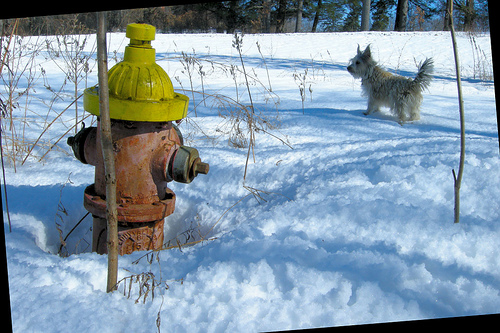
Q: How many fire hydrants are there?
A: One.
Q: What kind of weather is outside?
A: Snowy.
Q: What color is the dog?
A: White.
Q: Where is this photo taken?
A: In a field.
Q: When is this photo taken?
A: Daytime.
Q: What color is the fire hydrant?
A: Yellow.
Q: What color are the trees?
A: Green.